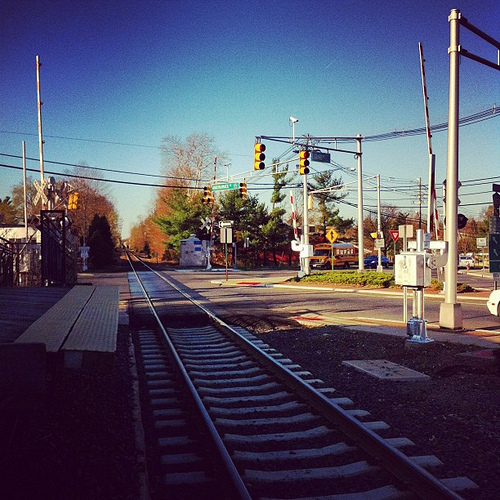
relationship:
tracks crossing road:
[135, 280, 325, 465] [81, 260, 279, 338]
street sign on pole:
[491, 235, 498, 272] [490, 275, 495, 292]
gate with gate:
[411, 40, 441, 252] [28, 54, 65, 238]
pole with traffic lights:
[427, 3, 474, 332] [225, 120, 340, 185]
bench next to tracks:
[19, 284, 124, 365] [122, 249, 478, 499]